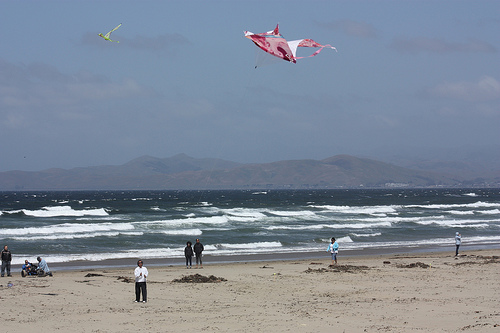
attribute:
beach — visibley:
[247, 304, 271, 320]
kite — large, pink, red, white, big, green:
[224, 18, 327, 60]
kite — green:
[98, 15, 139, 49]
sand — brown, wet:
[244, 299, 270, 313]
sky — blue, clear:
[398, 8, 417, 27]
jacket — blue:
[321, 230, 338, 252]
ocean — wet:
[191, 198, 222, 220]